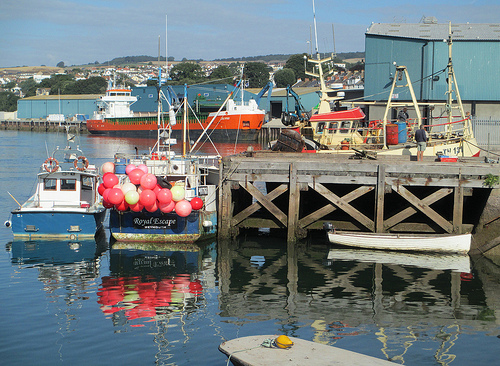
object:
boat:
[5, 139, 106, 237]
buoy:
[5, 221, 12, 228]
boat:
[322, 221, 471, 255]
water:
[0, 128, 500, 365]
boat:
[86, 68, 265, 140]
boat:
[262, 22, 480, 157]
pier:
[217, 150, 500, 256]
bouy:
[274, 335, 294, 349]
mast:
[446, 21, 453, 138]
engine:
[193, 93, 226, 112]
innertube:
[44, 157, 59, 172]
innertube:
[74, 156, 89, 171]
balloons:
[98, 162, 203, 217]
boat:
[95, 155, 219, 245]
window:
[60, 178, 76, 191]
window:
[43, 177, 57, 191]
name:
[134, 217, 177, 229]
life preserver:
[44, 156, 89, 172]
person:
[415, 124, 426, 161]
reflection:
[97, 274, 202, 320]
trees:
[0, 52, 366, 112]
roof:
[310, 106, 367, 121]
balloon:
[190, 197, 204, 209]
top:
[17, 170, 102, 211]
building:
[17, 94, 103, 119]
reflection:
[5, 236, 102, 303]